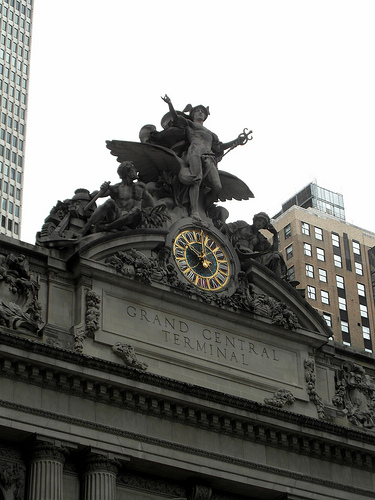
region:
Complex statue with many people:
[59, 103, 300, 284]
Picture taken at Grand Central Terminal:
[117, 304, 302, 379]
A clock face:
[164, 220, 243, 295]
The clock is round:
[165, 211, 245, 303]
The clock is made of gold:
[163, 219, 243, 293]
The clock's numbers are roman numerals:
[174, 226, 237, 291]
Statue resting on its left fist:
[234, 212, 284, 256]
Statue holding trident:
[173, 97, 255, 204]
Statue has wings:
[104, 139, 261, 203]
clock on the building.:
[173, 221, 237, 292]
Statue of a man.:
[160, 89, 254, 223]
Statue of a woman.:
[227, 210, 288, 276]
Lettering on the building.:
[117, 301, 282, 374]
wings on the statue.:
[103, 135, 256, 214]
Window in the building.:
[313, 244, 325, 263]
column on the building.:
[24, 444, 64, 499]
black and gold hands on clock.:
[172, 225, 237, 295]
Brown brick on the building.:
[272, 226, 372, 348]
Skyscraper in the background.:
[0, 0, 34, 243]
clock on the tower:
[153, 221, 228, 282]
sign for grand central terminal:
[121, 296, 316, 382]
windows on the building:
[302, 230, 363, 316]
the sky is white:
[235, 37, 331, 90]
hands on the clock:
[189, 247, 213, 270]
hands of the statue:
[225, 133, 265, 150]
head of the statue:
[185, 102, 208, 122]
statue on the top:
[139, 83, 220, 216]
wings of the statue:
[215, 170, 261, 208]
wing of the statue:
[101, 143, 170, 176]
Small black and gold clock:
[168, 217, 238, 297]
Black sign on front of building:
[91, 279, 325, 411]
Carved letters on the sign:
[117, 300, 293, 376]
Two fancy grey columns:
[24, 431, 127, 499]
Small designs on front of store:
[2, 253, 373, 428]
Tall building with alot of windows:
[256, 173, 373, 344]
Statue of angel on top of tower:
[142, 76, 251, 258]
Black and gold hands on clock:
[181, 226, 211, 272]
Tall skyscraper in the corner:
[0, 1, 49, 237]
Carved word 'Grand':
[115, 298, 200, 336]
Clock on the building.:
[129, 164, 276, 325]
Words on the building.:
[88, 267, 325, 415]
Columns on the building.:
[17, 422, 144, 499]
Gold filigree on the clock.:
[158, 197, 254, 320]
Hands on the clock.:
[169, 220, 230, 291]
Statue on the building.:
[142, 77, 273, 274]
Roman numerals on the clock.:
[166, 216, 280, 331]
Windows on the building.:
[277, 208, 373, 315]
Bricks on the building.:
[287, 193, 374, 322]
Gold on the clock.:
[167, 216, 250, 309]